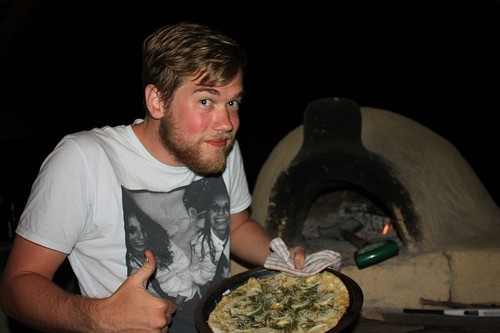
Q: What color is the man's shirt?
A: White.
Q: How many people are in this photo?
A: One.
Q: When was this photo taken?
A: Nighttime.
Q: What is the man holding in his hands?
A: Pizza.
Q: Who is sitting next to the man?
A: No one.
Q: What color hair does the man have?
A: Brown.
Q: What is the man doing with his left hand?
A: Thumbs-up.